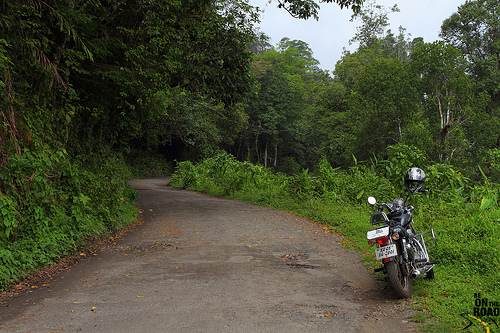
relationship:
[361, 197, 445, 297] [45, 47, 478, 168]
motorcycle in woods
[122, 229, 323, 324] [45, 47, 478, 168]
paved pathway woods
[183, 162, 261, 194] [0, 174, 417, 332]
green around pathway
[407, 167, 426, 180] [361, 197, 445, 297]
silver on bike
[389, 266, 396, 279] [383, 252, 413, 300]
black back tire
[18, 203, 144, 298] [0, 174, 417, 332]
leaves side of pathway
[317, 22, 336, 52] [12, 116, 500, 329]
blue above park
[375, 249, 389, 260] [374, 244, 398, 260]
white license plate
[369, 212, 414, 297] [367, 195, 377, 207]
rear view mirror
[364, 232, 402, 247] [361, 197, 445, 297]
tail lights on bike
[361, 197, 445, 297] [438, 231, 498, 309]
motorcycle parked grass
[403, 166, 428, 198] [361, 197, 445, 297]
helmet on motorcycle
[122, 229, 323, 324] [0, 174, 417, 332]
paved winding pathway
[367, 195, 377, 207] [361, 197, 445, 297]
mirror on bike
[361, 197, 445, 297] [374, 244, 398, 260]
motorcycle license plate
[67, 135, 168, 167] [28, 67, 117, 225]
thick patch of foliage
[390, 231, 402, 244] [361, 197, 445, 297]
blinker on motorcycle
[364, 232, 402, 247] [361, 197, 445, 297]
tail lights on motorcycle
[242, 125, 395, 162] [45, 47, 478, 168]
patch of trees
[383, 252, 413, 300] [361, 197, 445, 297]
wheel on motorcycle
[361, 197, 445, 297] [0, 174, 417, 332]
motorcycle on pathway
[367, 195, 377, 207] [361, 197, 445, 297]
mirror on motorcycle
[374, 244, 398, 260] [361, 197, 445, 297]
tag on motorcycle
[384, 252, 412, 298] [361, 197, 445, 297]
tire of motorcycle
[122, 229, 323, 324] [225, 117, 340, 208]
paved in middle of vegetaion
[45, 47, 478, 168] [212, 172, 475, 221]
trees on field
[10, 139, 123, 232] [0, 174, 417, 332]
bushes on pathway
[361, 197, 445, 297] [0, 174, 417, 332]
motorcycle of pathway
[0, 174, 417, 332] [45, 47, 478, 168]
pathway leading into woods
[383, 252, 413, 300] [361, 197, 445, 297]
tire rear bike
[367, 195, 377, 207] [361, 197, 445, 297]
mirror of bike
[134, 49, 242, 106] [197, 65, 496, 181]
leafy dark treeline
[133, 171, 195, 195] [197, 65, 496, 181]
pathway into wooded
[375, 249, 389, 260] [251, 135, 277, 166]
white tree trunks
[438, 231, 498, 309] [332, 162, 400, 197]
grass and vegetation